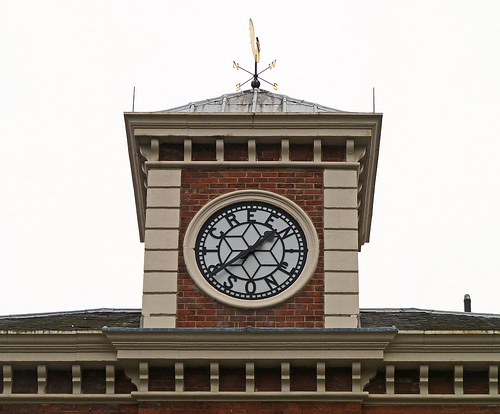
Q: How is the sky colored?
A: White.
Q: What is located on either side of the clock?
A: White shingles.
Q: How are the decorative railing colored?
A: White.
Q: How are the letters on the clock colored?
A: Black.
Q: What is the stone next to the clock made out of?
A: Concrete.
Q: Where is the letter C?
A: On the clock.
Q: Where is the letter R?
A: On the clock.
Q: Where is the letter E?
A: On the clock.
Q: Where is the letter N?
A: On the clock.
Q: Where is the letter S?
A: On the clock.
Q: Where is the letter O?
A: On the clock.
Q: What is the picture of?
A: A clock.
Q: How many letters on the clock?
A: Twelve.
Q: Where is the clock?
A: On the building.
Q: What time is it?
A: Daytime.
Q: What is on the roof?
A: A weather vane.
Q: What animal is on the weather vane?
A: Rooster.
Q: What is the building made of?
A: Brick.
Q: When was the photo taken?
A: During the day.